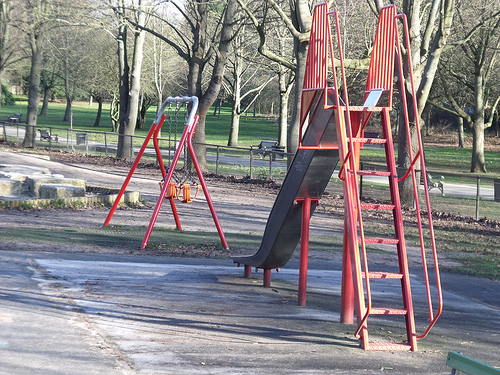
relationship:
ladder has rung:
[335, 105, 443, 353] [347, 137, 387, 145]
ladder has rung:
[335, 105, 443, 353] [355, 170, 391, 177]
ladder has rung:
[335, 105, 443, 353] [360, 203, 395, 211]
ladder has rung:
[335, 105, 443, 353] [359, 237, 399, 244]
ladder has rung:
[335, 105, 443, 353] [362, 270, 404, 279]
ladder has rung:
[335, 105, 443, 353] [366, 307, 408, 315]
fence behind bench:
[0, 120, 498, 229] [38, 128, 57, 142]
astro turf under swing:
[90, 223, 346, 252] [97, 94, 230, 251]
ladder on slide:
[335, 105, 443, 353] [233, 3, 445, 353]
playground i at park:
[1, 124, 498, 372] [4, 1, 494, 373]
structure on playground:
[0, 170, 140, 210] [4, 2, 485, 363]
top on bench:
[450, 356, 499, 373] [439, 347, 496, 374]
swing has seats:
[97, 96, 230, 252] [157, 179, 198, 203]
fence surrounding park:
[0, 120, 498, 229] [1, 151, 498, 371]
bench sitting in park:
[250, 140, 275, 154] [4, 1, 494, 373]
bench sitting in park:
[37, 129, 57, 142] [4, 1, 494, 373]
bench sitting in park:
[420, 168, 442, 195] [4, 1, 494, 373]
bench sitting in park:
[8, 112, 19, 124] [4, 1, 494, 373]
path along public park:
[100, 130, 206, 240] [4, 119, 498, 372]